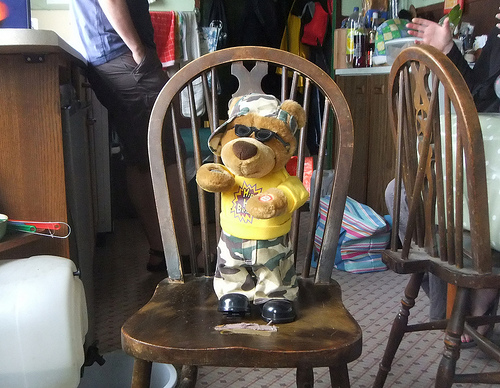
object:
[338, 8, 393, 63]
bottles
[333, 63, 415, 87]
counter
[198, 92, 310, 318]
teddybear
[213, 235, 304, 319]
pants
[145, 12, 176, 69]
towel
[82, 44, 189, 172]
shorts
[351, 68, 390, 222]
cabinet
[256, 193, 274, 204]
red button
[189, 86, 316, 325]
bear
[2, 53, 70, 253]
woodgrain surface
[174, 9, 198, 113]
towels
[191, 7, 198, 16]
holder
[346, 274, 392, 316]
carpeting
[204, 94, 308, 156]
hat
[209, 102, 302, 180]
head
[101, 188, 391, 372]
seat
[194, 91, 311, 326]
bear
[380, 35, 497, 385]
chair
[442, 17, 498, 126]
person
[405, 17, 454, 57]
hand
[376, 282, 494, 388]
foot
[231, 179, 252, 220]
logo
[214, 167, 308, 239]
shirt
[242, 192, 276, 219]
hand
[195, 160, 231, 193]
hand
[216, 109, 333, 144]
toy sunglasses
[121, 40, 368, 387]
chair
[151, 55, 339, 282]
chair back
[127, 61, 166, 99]
pocket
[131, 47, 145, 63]
hand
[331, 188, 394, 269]
striped bag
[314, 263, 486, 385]
floor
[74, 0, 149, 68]
shirt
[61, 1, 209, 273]
person